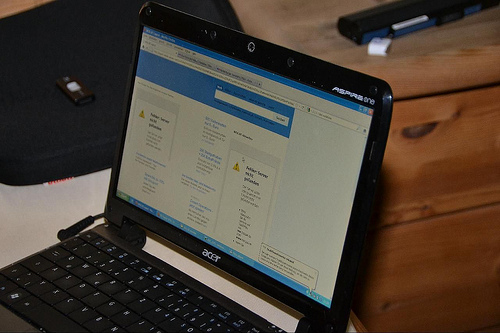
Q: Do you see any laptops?
A: Yes, there is a laptop.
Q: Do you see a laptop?
A: Yes, there is a laptop.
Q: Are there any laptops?
A: Yes, there is a laptop.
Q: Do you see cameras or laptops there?
A: Yes, there is a laptop.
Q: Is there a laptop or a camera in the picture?
A: Yes, there is a laptop.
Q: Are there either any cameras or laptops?
A: Yes, there is a laptop.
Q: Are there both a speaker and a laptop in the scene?
A: No, there is a laptop but no speakers.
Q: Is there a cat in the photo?
A: No, there are no cats.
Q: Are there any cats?
A: No, there are no cats.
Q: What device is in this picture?
A: The device is a laptop.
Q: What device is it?
A: The device is a laptop.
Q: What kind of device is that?
A: This is a laptop.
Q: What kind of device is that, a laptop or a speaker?
A: This is a laptop.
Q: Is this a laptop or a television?
A: This is a laptop.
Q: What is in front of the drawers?
A: The laptop computer is in front of the drawers.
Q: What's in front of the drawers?
A: The laptop computer is in front of the drawers.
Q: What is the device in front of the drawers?
A: The device is a laptop.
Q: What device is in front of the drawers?
A: The device is a laptop.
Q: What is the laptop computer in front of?
A: The laptop computer is in front of the drawers.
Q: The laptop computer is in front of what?
A: The laptop computer is in front of the drawers.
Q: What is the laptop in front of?
A: The laptop computer is in front of the drawers.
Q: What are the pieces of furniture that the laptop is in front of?
A: The pieces of furniture are drawers.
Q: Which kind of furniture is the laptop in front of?
A: The laptop is in front of the drawers.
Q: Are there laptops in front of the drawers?
A: Yes, there is a laptop in front of the drawers.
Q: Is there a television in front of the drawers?
A: No, there is a laptop in front of the drawers.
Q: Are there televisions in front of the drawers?
A: No, there is a laptop in front of the drawers.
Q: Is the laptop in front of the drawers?
A: Yes, the laptop is in front of the drawers.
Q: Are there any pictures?
A: No, there are no pictures.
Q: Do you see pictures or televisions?
A: No, there are no pictures or televisions.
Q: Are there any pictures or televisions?
A: No, there are no pictures or televisions.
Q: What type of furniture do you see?
A: The furniture is drawers.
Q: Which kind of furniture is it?
A: The pieces of furniture are drawers.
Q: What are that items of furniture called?
A: These are drawers.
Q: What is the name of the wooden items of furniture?
A: The pieces of furniture are drawers.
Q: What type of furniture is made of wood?
A: The furniture is drawers.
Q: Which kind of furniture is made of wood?
A: The furniture is drawers.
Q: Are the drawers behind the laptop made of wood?
A: Yes, the drawers are made of wood.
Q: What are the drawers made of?
A: The drawers are made of wood.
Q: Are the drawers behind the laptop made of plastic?
A: No, the drawers are made of wood.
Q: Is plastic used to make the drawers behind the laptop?
A: No, the drawers are made of wood.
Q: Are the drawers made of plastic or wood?
A: The drawers are made of wood.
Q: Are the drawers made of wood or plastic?
A: The drawers are made of wood.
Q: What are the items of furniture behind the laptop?
A: The pieces of furniture are drawers.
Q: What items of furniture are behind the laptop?
A: The pieces of furniture are drawers.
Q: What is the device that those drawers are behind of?
A: The device is a laptop.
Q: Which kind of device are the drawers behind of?
A: The drawers are behind the laptop.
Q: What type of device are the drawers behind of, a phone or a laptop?
A: The drawers are behind a laptop.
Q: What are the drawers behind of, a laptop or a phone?
A: The drawers are behind a laptop.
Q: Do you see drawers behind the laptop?
A: Yes, there are drawers behind the laptop.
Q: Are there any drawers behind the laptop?
A: Yes, there are drawers behind the laptop.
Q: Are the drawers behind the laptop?
A: Yes, the drawers are behind the laptop.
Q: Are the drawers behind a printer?
A: No, the drawers are behind the laptop.